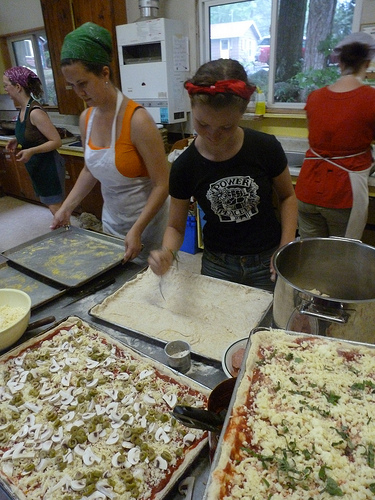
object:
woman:
[293, 35, 373, 247]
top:
[298, 86, 374, 211]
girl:
[147, 57, 299, 287]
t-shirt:
[171, 133, 288, 254]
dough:
[92, 261, 282, 371]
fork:
[156, 274, 168, 310]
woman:
[47, 23, 171, 259]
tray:
[12, 218, 133, 290]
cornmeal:
[37, 235, 113, 279]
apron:
[77, 104, 165, 240]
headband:
[182, 75, 255, 98]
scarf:
[58, 23, 114, 70]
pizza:
[211, 323, 374, 499]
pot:
[273, 229, 374, 341]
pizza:
[1, 320, 220, 499]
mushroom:
[90, 345, 105, 363]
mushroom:
[69, 425, 86, 444]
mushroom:
[73, 477, 98, 495]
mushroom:
[154, 406, 165, 424]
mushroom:
[140, 442, 152, 464]